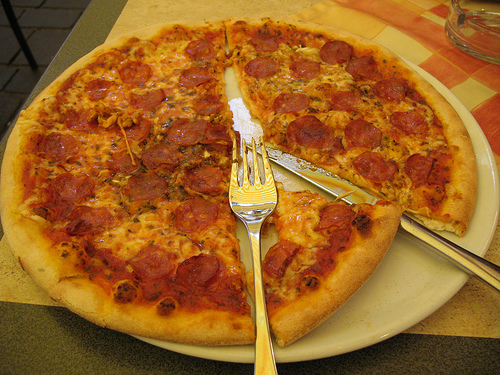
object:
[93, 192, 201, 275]
cheese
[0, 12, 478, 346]
pizza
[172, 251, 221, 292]
pepperoni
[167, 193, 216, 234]
pepperoni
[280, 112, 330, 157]
pepperoni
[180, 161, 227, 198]
pepperoni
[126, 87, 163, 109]
pepperoni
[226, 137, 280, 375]
fork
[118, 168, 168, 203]
pepperoni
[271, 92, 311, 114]
pepperoni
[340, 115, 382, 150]
pepperoni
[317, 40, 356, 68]
pepperoni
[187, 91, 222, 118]
pepperoni